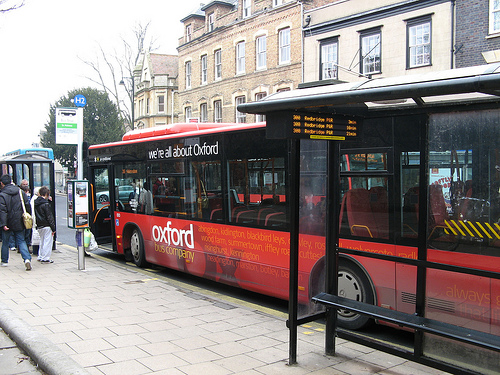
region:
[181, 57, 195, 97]
Small window on a building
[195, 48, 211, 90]
Small window on a building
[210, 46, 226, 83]
Small window on a building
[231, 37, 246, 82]
Small window on a building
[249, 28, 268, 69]
Small window on a building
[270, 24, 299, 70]
Small window on a building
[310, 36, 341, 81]
Small window on a building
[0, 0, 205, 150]
light in daytime sky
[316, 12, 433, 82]
three windows in black frames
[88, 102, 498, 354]
side of red bus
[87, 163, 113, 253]
open door of bus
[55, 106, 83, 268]
sign on metal pole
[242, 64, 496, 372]
bus shelter with bench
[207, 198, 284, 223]
seats inside of bus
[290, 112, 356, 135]
yellow words of display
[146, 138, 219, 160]
white message on black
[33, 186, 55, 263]
standing woman in black jacket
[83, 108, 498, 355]
a red public service bus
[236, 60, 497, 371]
a public service bus shelter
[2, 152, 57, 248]
a public service bus shelter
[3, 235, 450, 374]
a block paved walkway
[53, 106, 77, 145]
a bus passenger informational sign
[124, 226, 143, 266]
a bus front tire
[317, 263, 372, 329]
a bus rear tire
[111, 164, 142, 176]
an electronic bus destination sign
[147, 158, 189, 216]
a bus passenger window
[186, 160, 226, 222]
a bus passenger window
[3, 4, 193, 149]
bright sky over trees and buildings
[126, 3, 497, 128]
buildings next to each other on same side of street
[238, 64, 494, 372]
empty bus shelter with black bench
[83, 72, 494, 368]
red bus stopped at curb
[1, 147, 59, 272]
people standing near bus shelter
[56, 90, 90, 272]
pole with signs on top and middle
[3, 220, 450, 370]
sidewalk covered with large gray pavers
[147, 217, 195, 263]
white and yellow writing on red background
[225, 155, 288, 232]
bus seats seen through bus window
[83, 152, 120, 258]
open bus door with black frame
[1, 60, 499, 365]
the sheds for people waiting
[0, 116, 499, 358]
the bus on road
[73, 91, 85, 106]
blue and white sign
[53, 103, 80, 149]
the white with green on it sign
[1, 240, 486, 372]
the tiled sidewalk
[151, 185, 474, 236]
seats on the bus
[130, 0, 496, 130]
buildings on side of bus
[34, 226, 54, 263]
a pair of white pants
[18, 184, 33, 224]
a tan bag on shoulder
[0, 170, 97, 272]
people on sidewalk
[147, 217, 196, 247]
white words on side of bus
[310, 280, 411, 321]
black seat at the bus stop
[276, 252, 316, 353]
black frames on the bus stop